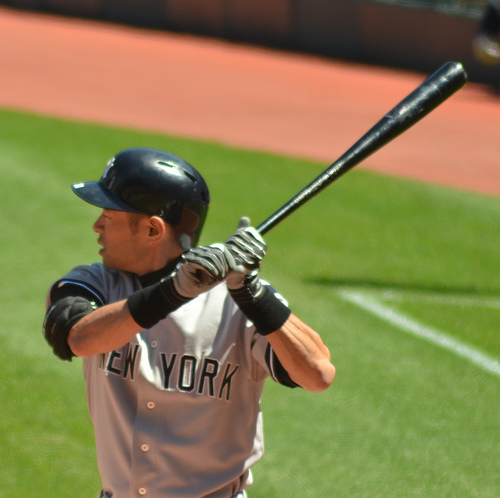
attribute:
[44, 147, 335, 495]
player — looking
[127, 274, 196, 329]
sweatband — black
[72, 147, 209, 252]
helmet — black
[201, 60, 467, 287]
bat — black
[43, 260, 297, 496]
outfit — gray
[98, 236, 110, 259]
mouth — open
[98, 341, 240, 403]
letters — black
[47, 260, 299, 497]
shirt — gray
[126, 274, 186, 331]
wristband — black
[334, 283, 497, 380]
line — white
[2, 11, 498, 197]
dirt — red, orage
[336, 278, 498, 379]
lines — painted white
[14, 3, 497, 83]
pad — gray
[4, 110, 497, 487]
grass — green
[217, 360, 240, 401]
letter — black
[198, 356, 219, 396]
letter — black